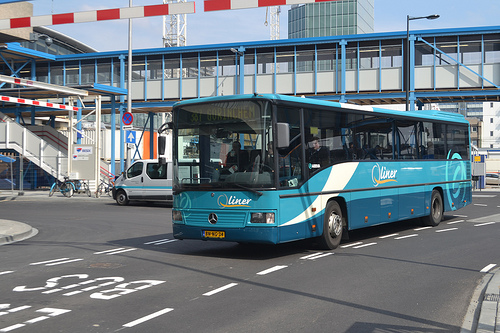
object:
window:
[169, 98, 280, 188]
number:
[189, 109, 195, 122]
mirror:
[276, 122, 291, 148]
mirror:
[157, 135, 167, 155]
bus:
[156, 92, 474, 250]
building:
[284, 0, 376, 39]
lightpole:
[404, 12, 411, 111]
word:
[380, 166, 398, 180]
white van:
[109, 158, 224, 206]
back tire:
[427, 187, 445, 227]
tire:
[321, 197, 345, 250]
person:
[225, 139, 250, 172]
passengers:
[305, 135, 331, 173]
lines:
[124, 114, 132, 123]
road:
[0, 186, 499, 332]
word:
[11, 271, 167, 302]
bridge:
[0, 24, 500, 120]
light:
[424, 12, 441, 20]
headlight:
[263, 212, 275, 225]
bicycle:
[48, 176, 77, 198]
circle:
[121, 111, 133, 128]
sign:
[119, 110, 135, 127]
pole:
[122, 0, 135, 170]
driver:
[257, 140, 285, 173]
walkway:
[1, 22, 500, 121]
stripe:
[277, 160, 361, 228]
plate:
[204, 230, 227, 239]